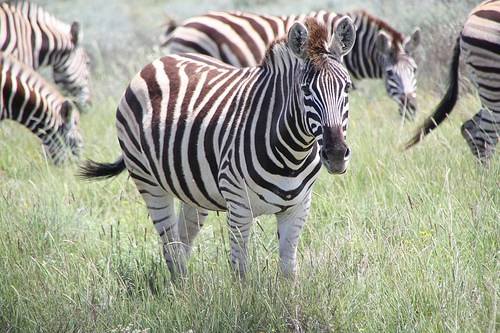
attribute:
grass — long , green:
[21, 59, 467, 326]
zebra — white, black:
[2, 65, 97, 147]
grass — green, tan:
[1, 1, 484, 330]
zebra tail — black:
[70, 150, 126, 186]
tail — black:
[406, 38, 463, 148]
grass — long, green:
[1, 74, 498, 331]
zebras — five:
[3, 7, 498, 175]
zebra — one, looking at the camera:
[114, 13, 369, 282]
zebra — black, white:
[82, 22, 354, 311]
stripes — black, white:
[167, 64, 257, 154]